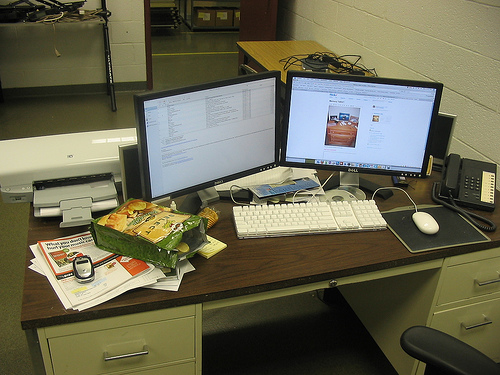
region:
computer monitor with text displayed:
[272, 64, 448, 186]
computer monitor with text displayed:
[127, 57, 288, 205]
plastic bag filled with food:
[82, 186, 219, 271]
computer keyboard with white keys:
[223, 188, 390, 246]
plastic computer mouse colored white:
[410, 206, 440, 239]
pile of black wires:
[266, 40, 380, 82]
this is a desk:
[6, 88, 497, 371]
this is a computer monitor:
[100, 49, 290, 213]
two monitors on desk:
[115, 34, 490, 291]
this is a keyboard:
[215, 171, 403, 266]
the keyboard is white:
[213, 186, 396, 241]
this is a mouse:
[378, 177, 463, 254]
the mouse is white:
[390, 188, 457, 248]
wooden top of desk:
[14, 125, 493, 325]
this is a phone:
[58, 248, 98, 296]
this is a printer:
[9, 100, 184, 249]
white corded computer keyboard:
[232, 198, 388, 236]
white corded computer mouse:
[374, 183, 440, 235]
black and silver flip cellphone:
[71, 251, 97, 285]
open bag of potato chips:
[88, 197, 209, 269]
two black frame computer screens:
[132, 68, 445, 201]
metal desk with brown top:
[20, 149, 499, 374]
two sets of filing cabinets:
[44, 246, 499, 371]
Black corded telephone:
[430, 150, 499, 235]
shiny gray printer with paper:
[1, 125, 138, 227]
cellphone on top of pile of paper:
[30, 224, 195, 311]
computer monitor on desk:
[265, 53, 450, 195]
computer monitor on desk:
[108, 64, 316, 218]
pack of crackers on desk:
[77, 178, 222, 303]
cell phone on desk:
[54, 243, 112, 295]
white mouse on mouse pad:
[397, 193, 462, 256]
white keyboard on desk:
[229, 180, 397, 254]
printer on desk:
[0, 121, 172, 237]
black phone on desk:
[431, 148, 498, 233]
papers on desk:
[22, 226, 177, 314]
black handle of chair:
[385, 313, 498, 373]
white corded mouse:
[413, 209, 439, 233]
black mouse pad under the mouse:
[384, 202, 491, 252]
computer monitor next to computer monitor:
[279, 70, 447, 193]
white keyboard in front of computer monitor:
[232, 198, 389, 239]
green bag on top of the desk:
[90, 196, 212, 270]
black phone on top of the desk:
[429, 152, 498, 232]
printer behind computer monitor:
[0, 125, 147, 226]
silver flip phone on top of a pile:
[72, 253, 94, 283]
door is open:
[238, 0, 283, 72]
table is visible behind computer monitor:
[235, 39, 376, 92]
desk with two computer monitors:
[22, 66, 499, 373]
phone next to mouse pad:
[383, 153, 498, 255]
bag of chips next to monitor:
[91, 193, 209, 267]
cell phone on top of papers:
[27, 227, 170, 308]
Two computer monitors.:
[116, 66, 441, 206]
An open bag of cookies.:
[91, 200, 211, 270]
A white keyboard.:
[231, 190, 388, 236]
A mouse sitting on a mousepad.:
[380, 203, 497, 254]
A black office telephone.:
[433, 150, 496, 237]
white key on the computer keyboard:
[240, 202, 250, 212]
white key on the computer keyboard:
[246, 202, 251, 207]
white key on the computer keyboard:
[255, 201, 260, 206]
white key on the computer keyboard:
[256, 197, 266, 207]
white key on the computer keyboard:
[272, 201, 277, 206]